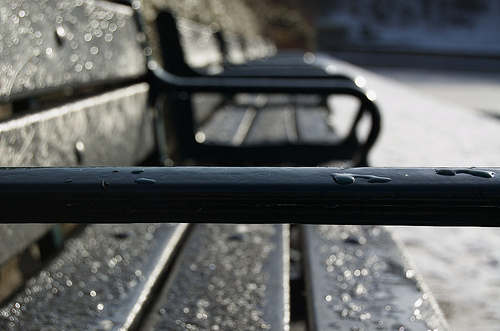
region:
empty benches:
[1, 0, 499, 329]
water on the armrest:
[327, 165, 394, 191]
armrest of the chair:
[0, 158, 499, 255]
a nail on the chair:
[50, 23, 70, 49]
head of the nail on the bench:
[341, 232, 373, 249]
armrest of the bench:
[140, 60, 385, 169]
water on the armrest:
[432, 163, 497, 180]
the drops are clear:
[312, 164, 487, 194]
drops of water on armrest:
[277, 160, 476, 215]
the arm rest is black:
[170, 70, 372, 165]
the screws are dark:
[54, 20, 99, 168]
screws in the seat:
[42, 17, 96, 172]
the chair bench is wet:
[75, 223, 405, 325]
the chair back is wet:
[5, 18, 143, 255]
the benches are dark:
[5, 10, 359, 327]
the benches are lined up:
[12, 17, 407, 320]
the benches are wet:
[9, 11, 387, 328]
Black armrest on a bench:
[69, 149, 487, 226]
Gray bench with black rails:
[76, 46, 408, 324]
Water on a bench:
[24, 33, 128, 133]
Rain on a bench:
[193, 235, 360, 322]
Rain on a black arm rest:
[313, 155, 444, 215]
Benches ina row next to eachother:
[148, 23, 398, 242]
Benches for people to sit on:
[197, 55, 420, 270]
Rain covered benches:
[34, 23, 361, 329]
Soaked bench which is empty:
[138, 133, 426, 325]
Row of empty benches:
[156, 17, 416, 231]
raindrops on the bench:
[12, 9, 407, 329]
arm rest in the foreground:
[9, 147, 498, 228]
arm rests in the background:
[153, 39, 376, 153]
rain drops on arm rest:
[126, 163, 494, 185]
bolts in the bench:
[53, 19, 363, 249]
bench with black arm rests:
[2, 0, 499, 330]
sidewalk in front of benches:
[325, 56, 499, 330]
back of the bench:
[3, 4, 157, 247]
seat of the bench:
[43, 163, 439, 330]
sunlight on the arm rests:
[305, 47, 377, 104]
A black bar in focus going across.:
[0, 163, 498, 227]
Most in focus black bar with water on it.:
[2, 164, 498, 226]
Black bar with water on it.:
[0, 164, 499, 223]